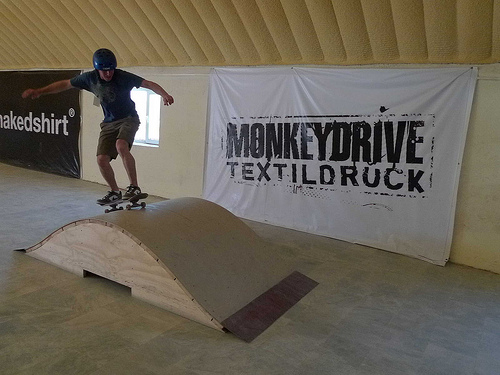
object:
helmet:
[92, 48, 118, 72]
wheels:
[140, 201, 147, 209]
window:
[129, 81, 160, 148]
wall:
[0, 64, 500, 275]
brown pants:
[95, 117, 140, 161]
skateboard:
[96, 193, 149, 214]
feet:
[121, 185, 142, 200]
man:
[19, 48, 175, 206]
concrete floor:
[0, 162, 497, 372]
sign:
[200, 63, 477, 265]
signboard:
[0, 68, 81, 179]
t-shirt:
[69, 68, 144, 124]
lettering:
[0, 109, 71, 139]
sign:
[1, 69, 78, 177]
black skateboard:
[95, 192, 148, 213]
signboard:
[198, 65, 478, 267]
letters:
[0, 109, 71, 136]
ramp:
[14, 196, 319, 345]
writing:
[221, 112, 442, 196]